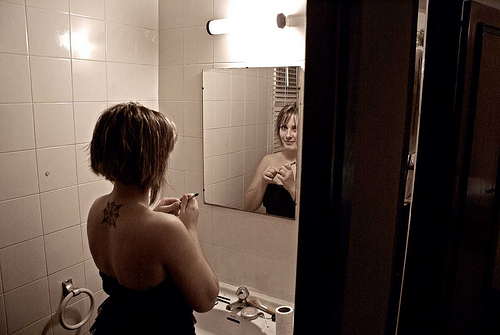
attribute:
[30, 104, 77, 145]
tile — modern, wall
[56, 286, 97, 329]
hanger — metal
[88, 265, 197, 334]
dress — black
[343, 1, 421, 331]
jamb — brown, wooden, door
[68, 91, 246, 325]
woman — young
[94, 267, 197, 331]
dress — black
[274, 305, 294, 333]
roll — pictured here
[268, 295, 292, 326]
tissue — toilet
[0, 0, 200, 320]
wall — tiled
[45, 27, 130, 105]
tiles — white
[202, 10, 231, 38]
light — on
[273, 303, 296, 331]
tissue — toilet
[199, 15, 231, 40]
light — very bright